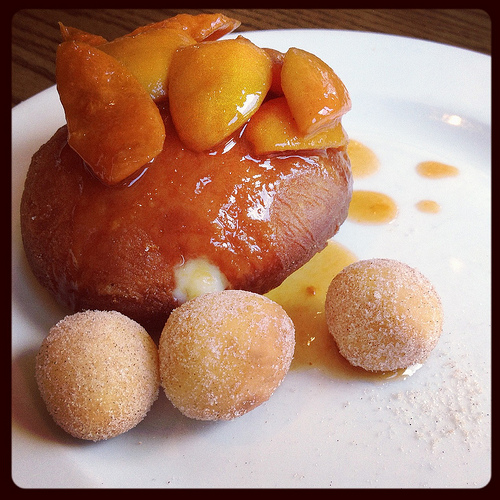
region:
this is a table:
[11, 21, 36, 90]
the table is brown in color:
[29, 30, 56, 81]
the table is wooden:
[437, 10, 468, 32]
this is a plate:
[171, 443, 233, 461]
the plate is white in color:
[165, 433, 233, 470]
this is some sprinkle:
[379, 385, 474, 440]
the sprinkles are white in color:
[386, 390, 487, 435]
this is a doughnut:
[187, 215, 261, 241]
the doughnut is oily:
[190, 171, 230, 199]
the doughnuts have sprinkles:
[76, 355, 136, 385]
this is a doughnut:
[164, 165, 298, 252]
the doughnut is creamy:
[145, 153, 266, 249]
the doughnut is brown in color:
[285, 180, 340, 245]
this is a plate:
[330, 402, 397, 484]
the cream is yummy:
[155, 147, 237, 222]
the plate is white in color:
[405, 82, 465, 122]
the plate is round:
[397, 43, 462, 118]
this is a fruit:
[327, 255, 452, 367]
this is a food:
[65, 53, 155, 163]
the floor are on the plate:
[399, 385, 474, 445]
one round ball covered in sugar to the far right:
[323, 261, 443, 369]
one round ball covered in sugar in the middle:
[168, 291, 296, 421]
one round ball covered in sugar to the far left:
[32, 309, 157, 436]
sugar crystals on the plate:
[398, 380, 490, 448]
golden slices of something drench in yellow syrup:
[47, 21, 349, 152]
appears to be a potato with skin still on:
[28, 160, 353, 252]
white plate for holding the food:
[376, 32, 477, 120]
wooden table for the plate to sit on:
[386, 10, 472, 37]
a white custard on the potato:
[161, 264, 233, 295]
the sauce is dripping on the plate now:
[354, 187, 391, 224]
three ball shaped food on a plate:
[26, 258, 446, 440]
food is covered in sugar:
[31, 307, 159, 443]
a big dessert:
[25, 98, 348, 308]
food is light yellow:
[40, 313, 163, 440]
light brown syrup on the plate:
[258, 230, 415, 383]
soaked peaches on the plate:
[52, 9, 350, 183]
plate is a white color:
[8, 23, 499, 488]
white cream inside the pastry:
[166, 254, 227, 283]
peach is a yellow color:
[53, 40, 167, 184]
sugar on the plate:
[371, 365, 498, 467]